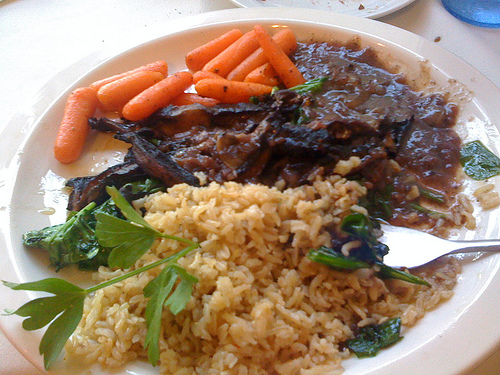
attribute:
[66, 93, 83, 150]
carrott — orange, whole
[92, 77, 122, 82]
carrott — orange, whole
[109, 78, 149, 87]
carrott — orange, whole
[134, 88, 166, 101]
carrott — orange, whole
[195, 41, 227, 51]
carrott — orange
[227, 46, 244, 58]
carrott — orange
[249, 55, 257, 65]
carrott — orange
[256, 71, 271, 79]
carrott — orange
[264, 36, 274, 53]
carrott — orange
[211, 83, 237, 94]
carrott — orange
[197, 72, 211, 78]
carrott — orange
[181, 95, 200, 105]
carrott — orange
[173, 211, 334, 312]
rice — white, cooked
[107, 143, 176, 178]
meat — brown, cooked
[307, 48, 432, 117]
sauce — brown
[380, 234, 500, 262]
fork — silver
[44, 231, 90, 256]
lettuce — green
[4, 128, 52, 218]
plate — white, round